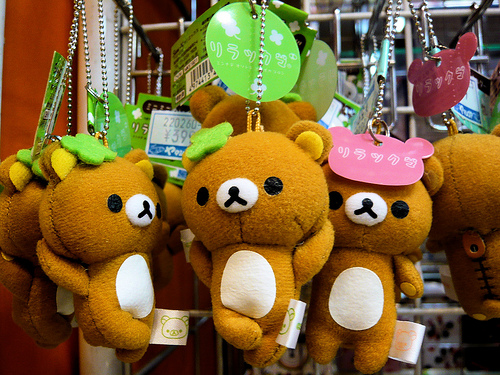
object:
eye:
[260, 175, 285, 197]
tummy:
[219, 248, 278, 321]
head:
[178, 118, 334, 253]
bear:
[177, 117, 335, 369]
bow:
[58, 131, 119, 167]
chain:
[243, 0, 273, 118]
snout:
[213, 176, 259, 215]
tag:
[326, 124, 436, 188]